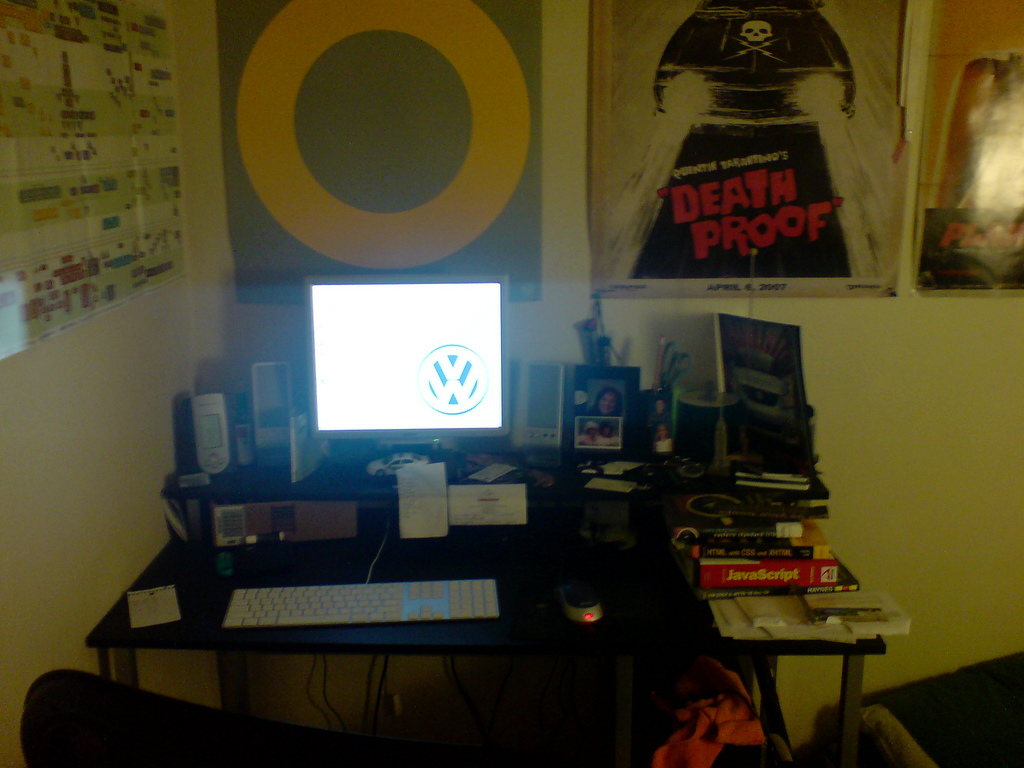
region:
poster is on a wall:
[588, 1, 917, 302]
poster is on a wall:
[213, 1, 542, 303]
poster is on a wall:
[3, 3, 181, 359]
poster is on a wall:
[914, 6, 1023, 294]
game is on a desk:
[680, 526, 824, 562]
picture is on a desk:
[573, 415, 621, 453]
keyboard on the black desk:
[223, 574, 502, 631]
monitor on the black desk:
[296, 271, 505, 442]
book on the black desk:
[694, 547, 843, 587]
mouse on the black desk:
[566, 575, 602, 629]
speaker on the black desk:
[190, 391, 239, 486]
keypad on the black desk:
[121, 576, 188, 641]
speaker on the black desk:
[516, 354, 573, 457]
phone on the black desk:
[168, 394, 210, 486]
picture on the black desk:
[570, 402, 624, 459]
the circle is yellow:
[221, 6, 550, 292]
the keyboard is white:
[208, 571, 519, 642]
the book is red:
[689, 551, 846, 603]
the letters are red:
[654, 151, 860, 273]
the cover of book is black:
[698, 298, 825, 442]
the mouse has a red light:
[553, 575, 618, 637]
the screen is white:
[300, 271, 512, 449]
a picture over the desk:
[553, 350, 646, 483]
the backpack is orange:
[647, 652, 778, 766]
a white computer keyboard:
[231, 572, 497, 626]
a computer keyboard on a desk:
[218, 556, 525, 642]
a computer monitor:
[294, 270, 530, 447]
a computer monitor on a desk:
[260, 266, 533, 542]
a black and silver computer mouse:
[548, 585, 632, 640]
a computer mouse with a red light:
[548, 570, 629, 648]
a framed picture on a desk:
[556, 364, 645, 457]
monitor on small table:
[275, 261, 510, 451]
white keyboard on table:
[218, 577, 503, 632]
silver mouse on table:
[548, 567, 597, 631]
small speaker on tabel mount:
[181, 382, 232, 477]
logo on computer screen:
[406, 344, 486, 420]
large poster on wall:
[203, 9, 564, 311]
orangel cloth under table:
[639, 653, 767, 765]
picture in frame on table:
[560, 360, 636, 462]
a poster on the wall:
[591, 22, 898, 291]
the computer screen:
[312, 282, 497, 420]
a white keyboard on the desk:
[223, 582, 509, 617]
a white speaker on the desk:
[192, 399, 232, 475]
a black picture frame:
[581, 370, 640, 432]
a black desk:
[107, 483, 896, 683]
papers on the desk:
[391, 461, 493, 532]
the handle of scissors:
[654, 342, 689, 380]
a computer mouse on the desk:
[561, 576, 600, 622]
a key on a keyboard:
[236, 601, 246, 609]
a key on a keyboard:
[232, 614, 243, 621]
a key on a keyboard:
[250, 618, 264, 620]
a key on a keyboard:
[269, 605, 277, 615]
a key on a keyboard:
[277, 605, 288, 616]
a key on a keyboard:
[308, 605, 325, 618]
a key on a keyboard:
[333, 602, 337, 607]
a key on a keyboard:
[343, 604, 356, 606]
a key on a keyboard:
[362, 604, 375, 618]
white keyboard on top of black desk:
[226, 572, 508, 631]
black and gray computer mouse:
[557, 578, 605, 629]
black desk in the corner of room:
[80, 425, 890, 764]